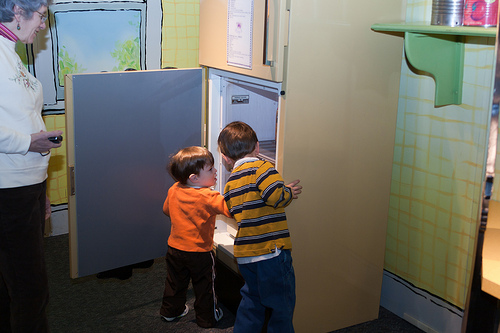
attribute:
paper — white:
[224, 0, 252, 69]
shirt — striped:
[225, 160, 296, 253]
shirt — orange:
[160, 173, 226, 254]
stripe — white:
[207, 245, 235, 327]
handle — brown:
[258, 2, 272, 66]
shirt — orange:
[165, 189, 225, 250]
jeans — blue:
[239, 254, 302, 331]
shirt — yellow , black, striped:
[225, 156, 292, 262]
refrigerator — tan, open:
[191, 2, 415, 155]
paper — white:
[224, 0, 257, 64]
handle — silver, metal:
[260, 7, 273, 64]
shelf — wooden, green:
[372, 14, 492, 45]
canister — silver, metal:
[432, 3, 462, 22]